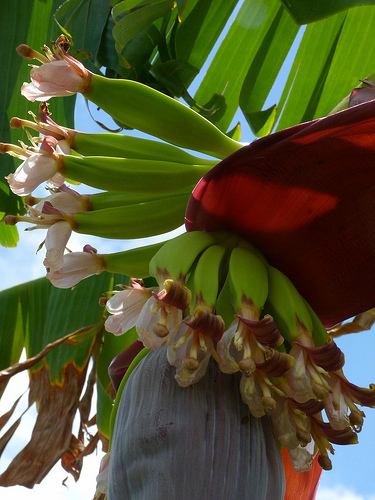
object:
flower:
[20, 33, 88, 102]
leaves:
[189, 21, 272, 141]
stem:
[81, 70, 250, 161]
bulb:
[14, 42, 49, 65]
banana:
[148, 230, 215, 289]